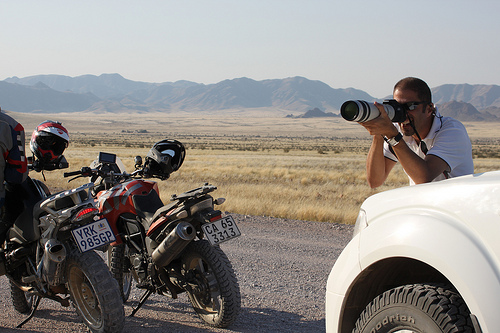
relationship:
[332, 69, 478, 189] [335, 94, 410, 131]
man holding camera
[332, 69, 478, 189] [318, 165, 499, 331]
man leaning on car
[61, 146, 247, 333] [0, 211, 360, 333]
motorcycle on gravel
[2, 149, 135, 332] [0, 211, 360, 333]
motorcycle on gravel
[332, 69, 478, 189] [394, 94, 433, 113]
man wearing glasses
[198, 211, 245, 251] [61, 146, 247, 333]
license plate on motorcycle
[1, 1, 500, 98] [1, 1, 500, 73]
clouds in clouds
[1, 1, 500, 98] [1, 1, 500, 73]
clouds are in clouds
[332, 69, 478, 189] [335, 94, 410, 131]
man with camera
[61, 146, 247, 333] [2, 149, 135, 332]
motorcycle next to motorcycle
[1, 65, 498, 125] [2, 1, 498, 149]
mountains in background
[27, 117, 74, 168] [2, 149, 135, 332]
helmet on motorcycle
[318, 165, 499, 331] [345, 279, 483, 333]
car has wheel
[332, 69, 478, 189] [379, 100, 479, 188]
man has shirt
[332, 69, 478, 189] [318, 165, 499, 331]
man in front of car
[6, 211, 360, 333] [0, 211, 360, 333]
gravel on gravel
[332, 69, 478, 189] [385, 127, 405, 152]
man has watch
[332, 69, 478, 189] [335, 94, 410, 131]
man taking picture with camera